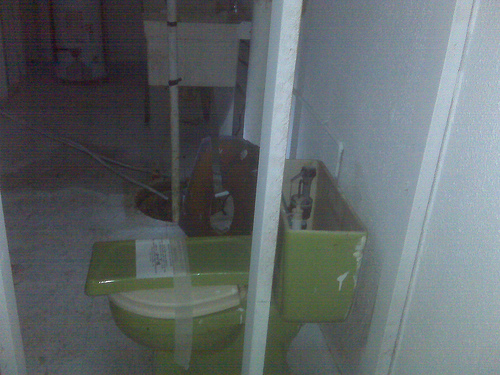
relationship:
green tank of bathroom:
[263, 147, 365, 321] [0, 0, 495, 372]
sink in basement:
[128, 15, 263, 96] [28, 29, 426, 351]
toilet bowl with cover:
[110, 284, 254, 364] [113, 287, 236, 312]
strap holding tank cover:
[162, 218, 196, 373] [83, 230, 255, 298]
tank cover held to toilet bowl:
[83, 230, 255, 298] [101, 280, 308, 374]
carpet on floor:
[20, 177, 87, 260] [1, 85, 155, 237]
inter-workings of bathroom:
[285, 162, 316, 229] [0, 0, 495, 372]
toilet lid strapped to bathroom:
[83, 227, 277, 306] [0, 0, 495, 372]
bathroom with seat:
[0, 0, 495, 372] [110, 284, 242, 315]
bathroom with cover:
[0, 0, 495, 372] [113, 287, 236, 320]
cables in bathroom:
[4, 93, 135, 177] [30, 19, 443, 364]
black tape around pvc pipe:
[161, 17, 180, 30] [163, 0, 184, 227]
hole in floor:
[128, 163, 198, 234] [6, 55, 328, 367]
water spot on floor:
[4, 137, 166, 213] [66, 160, 402, 367]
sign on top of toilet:
[130, 234, 180, 275] [71, 227, 291, 359]